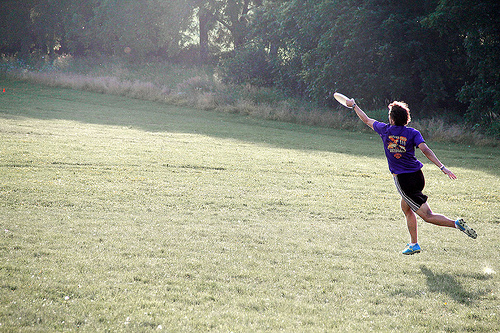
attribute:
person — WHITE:
[347, 85, 476, 255]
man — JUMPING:
[342, 88, 477, 258]